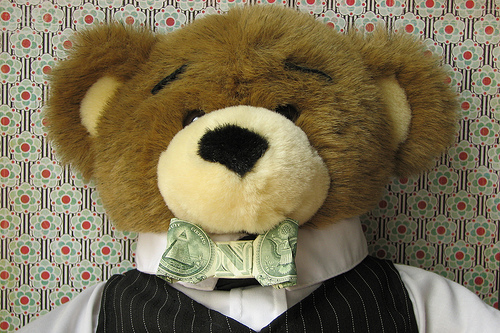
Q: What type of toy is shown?
A: A teddy bear.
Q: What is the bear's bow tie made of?
A: A dollar bill.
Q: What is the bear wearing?
A: A vest and white shirt.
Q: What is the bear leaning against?
A: Wall paper.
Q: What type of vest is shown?
A: Pinstripe.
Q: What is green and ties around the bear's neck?
A: A dollar.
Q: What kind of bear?
A: Teddy bear.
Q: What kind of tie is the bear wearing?
A: Bowtie.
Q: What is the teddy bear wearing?
A: Vest.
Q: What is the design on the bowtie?
A: Money.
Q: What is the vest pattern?
A: Striped.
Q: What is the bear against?
A: Wall.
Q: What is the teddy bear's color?
A: Brown.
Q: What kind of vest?
A: Pinstripe.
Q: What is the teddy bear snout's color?
A: Cream.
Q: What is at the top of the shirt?
A: Collar.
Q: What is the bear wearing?
A: Formal clothes.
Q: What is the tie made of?
A: Money.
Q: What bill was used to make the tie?
A: One dollar.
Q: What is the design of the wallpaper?
A: Floral.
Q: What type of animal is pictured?
A: Teddy bear.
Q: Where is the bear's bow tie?
A: On bear's necks.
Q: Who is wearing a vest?
A: The bear.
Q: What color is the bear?
A: Brown.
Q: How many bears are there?
A: One baer.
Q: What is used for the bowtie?
A: A dollar.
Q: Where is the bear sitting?
A: Against the wall.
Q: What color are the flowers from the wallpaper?
A: Red and green.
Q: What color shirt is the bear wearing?
A: White.